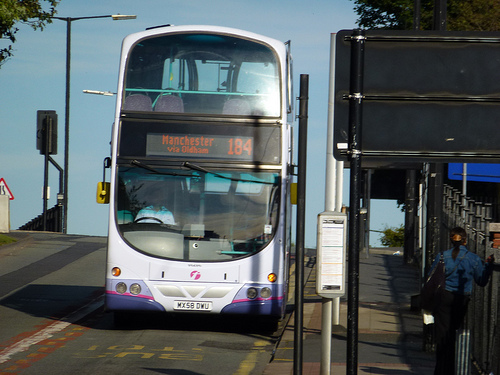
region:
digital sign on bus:
[133, 120, 268, 173]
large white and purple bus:
[96, 17, 300, 339]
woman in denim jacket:
[408, 212, 492, 368]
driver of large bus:
[114, 184, 188, 239]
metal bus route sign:
[296, 192, 371, 322]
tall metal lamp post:
[8, 1, 144, 244]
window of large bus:
[102, 152, 293, 284]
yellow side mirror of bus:
[90, 166, 117, 216]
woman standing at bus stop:
[314, 8, 496, 373]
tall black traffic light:
[19, 90, 78, 237]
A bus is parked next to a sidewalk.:
[97, 16, 309, 334]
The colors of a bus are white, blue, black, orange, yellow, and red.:
[92, 13, 307, 341]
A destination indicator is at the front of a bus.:
[120, 116, 285, 171]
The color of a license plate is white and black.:
[164, 293, 219, 315]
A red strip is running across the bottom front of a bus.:
[100, 281, 292, 309]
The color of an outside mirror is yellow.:
[90, 173, 112, 213]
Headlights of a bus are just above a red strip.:
[105, 276, 278, 305]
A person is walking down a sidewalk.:
[410, 212, 498, 372]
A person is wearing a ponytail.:
[441, 222, 466, 263]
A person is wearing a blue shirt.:
[420, 236, 491, 308]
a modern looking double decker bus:
[85, 19, 299, 334]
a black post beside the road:
[270, 66, 313, 373]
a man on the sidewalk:
[403, 222, 498, 368]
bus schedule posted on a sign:
[312, 207, 349, 302]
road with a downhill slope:
[1, 227, 440, 373]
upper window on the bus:
[119, 32, 281, 117]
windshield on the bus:
[111, 162, 279, 270]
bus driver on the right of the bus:
[113, 175, 185, 282]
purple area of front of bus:
[100, 279, 284, 316]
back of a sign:
[332, 19, 498, 163]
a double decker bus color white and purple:
[93, 19, 303, 342]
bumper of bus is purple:
[95, 278, 285, 323]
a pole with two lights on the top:
[12, 2, 137, 226]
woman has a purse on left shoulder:
[407, 217, 497, 369]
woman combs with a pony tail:
[438, 218, 473, 268]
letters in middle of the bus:
[136, 122, 268, 165]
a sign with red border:
[0, 172, 19, 209]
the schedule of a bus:
[306, 199, 348, 374]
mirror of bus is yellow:
[89, 156, 118, 213]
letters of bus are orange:
[143, 120, 262, 168]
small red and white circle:
[183, 269, 210, 290]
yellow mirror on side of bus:
[83, 169, 116, 206]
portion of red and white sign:
[5, 169, 24, 202]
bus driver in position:
[138, 183, 179, 250]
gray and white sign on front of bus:
[145, 278, 245, 301]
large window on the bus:
[103, 152, 288, 267]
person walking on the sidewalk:
[427, 223, 488, 323]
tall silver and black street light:
[70, 5, 180, 32]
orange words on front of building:
[135, 125, 273, 163]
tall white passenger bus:
[89, 20, 293, 324]